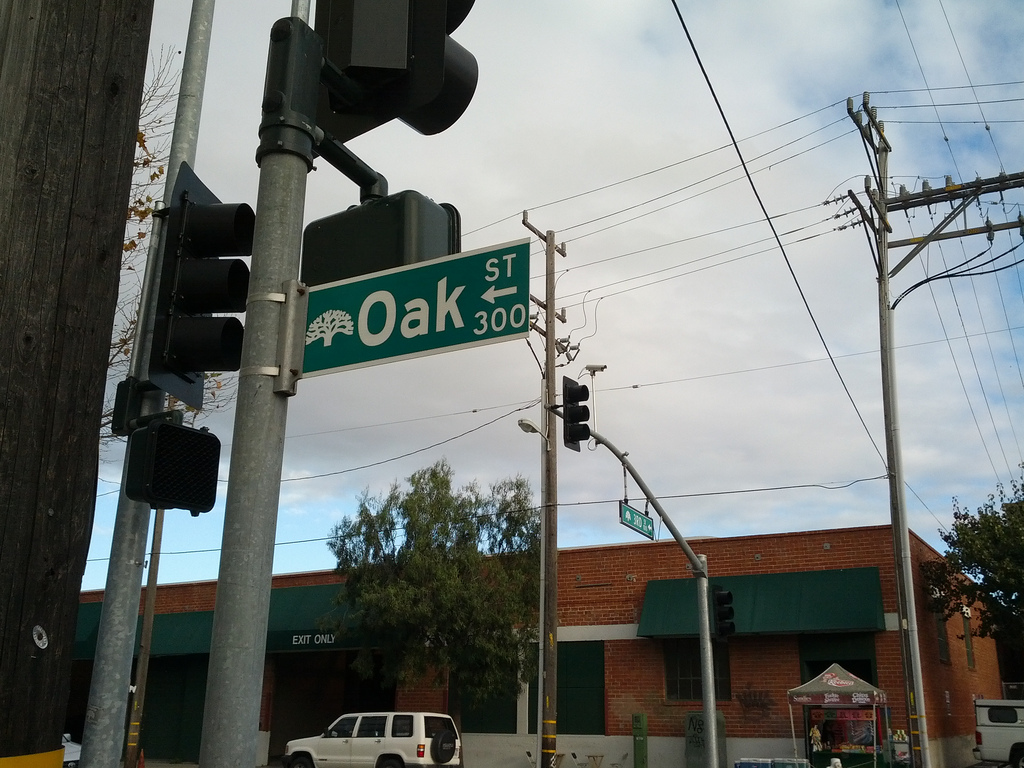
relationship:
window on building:
[660, 636, 734, 704] [67, 525, 1022, 766]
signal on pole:
[118, 173, 276, 422] [854, 314, 979, 761]